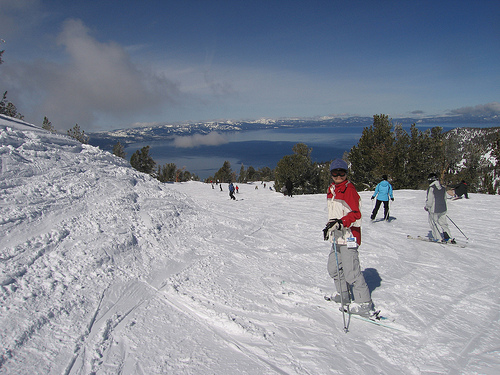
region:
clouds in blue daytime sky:
[0, 1, 498, 128]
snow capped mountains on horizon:
[92, 112, 496, 144]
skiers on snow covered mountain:
[1, 115, 496, 373]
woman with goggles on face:
[320, 159, 378, 316]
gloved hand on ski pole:
[323, 217, 352, 332]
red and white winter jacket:
[327, 180, 362, 247]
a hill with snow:
[1, 110, 491, 368]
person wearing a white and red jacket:
[308, 151, 379, 333]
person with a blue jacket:
[367, 170, 399, 223]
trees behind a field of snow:
[18, 104, 495, 253]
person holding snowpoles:
[309, 154, 381, 335]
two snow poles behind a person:
[416, 164, 469, 255]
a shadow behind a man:
[315, 155, 390, 330]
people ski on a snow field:
[173, 158, 283, 213]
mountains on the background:
[88, 110, 473, 144]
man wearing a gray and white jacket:
[416, 164, 473, 252]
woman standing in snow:
[313, 153, 395, 325]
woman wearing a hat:
[325, 158, 352, 177]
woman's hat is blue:
[328, 155, 350, 171]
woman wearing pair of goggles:
[329, 165, 347, 180]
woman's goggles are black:
[328, 167, 349, 179]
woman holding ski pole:
[326, 224, 358, 334]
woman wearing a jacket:
[321, 178, 365, 251]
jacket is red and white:
[321, 178, 366, 249]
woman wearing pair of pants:
[323, 241, 375, 312]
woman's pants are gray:
[325, 238, 376, 313]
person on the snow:
[423, 168, 460, 247]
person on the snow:
[368, 178, 396, 221]